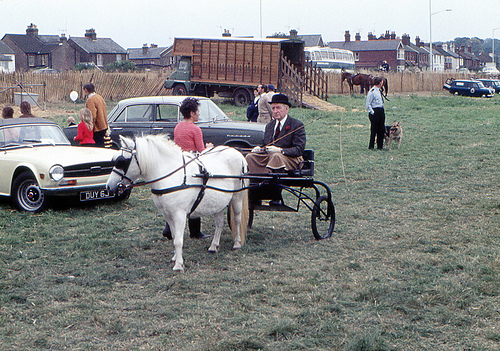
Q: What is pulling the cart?
A: Pony.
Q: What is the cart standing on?
A: Grass.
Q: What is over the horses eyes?
A: Black blinders.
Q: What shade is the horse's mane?
A: White.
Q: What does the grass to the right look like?
A: Green and short.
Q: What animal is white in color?
A: Horse.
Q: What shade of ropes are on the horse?
A: Black.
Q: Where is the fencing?
A: On back of truck.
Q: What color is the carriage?
A: Black.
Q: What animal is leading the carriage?
A: Horse.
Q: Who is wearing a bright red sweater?
A: Person with long blond hair.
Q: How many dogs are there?
A: 1.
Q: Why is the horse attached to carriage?
A: It is leading it.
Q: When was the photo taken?
A: Daytime.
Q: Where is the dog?
A: By man in blue shirt.